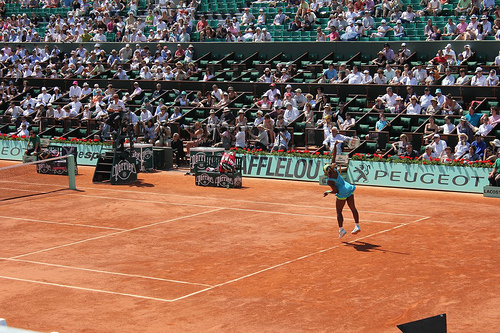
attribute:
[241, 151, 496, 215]
sign — green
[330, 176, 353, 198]
tennis outfit — blue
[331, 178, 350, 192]
shirt — blue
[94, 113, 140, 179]
stand — green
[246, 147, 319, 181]
letters — black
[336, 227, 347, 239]
shoe — white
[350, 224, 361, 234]
shoe — white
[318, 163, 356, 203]
dress — teal, tennis